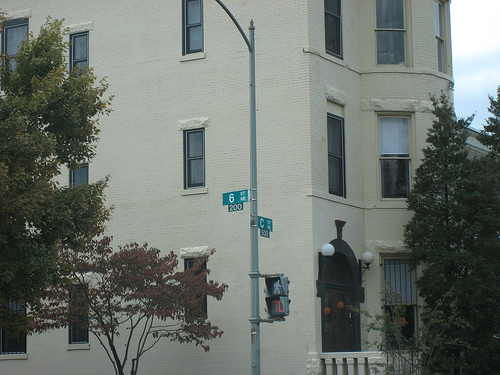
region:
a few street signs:
[218, 185, 279, 245]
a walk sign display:
[258, 273, 290, 296]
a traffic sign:
[263, 272, 298, 319]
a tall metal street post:
[236, 50, 265, 363]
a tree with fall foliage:
[31, 234, 228, 370]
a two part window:
[177, 119, 217, 197]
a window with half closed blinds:
[376, 101, 416, 212]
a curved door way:
[318, 234, 370, 366]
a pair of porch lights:
[317, 244, 374, 273]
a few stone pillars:
[318, 350, 384, 371]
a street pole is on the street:
[244, 22, 263, 372]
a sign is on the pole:
[219, 187, 250, 209]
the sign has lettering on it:
[223, 188, 246, 206]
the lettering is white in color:
[223, 187, 248, 202]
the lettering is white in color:
[255, 215, 270, 232]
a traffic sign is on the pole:
[263, 272, 292, 299]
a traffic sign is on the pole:
[263, 295, 291, 317]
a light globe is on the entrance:
[322, 241, 333, 256]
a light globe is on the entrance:
[362, 250, 372, 261]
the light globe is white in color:
[322, 245, 335, 257]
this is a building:
[110, 15, 408, 254]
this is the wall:
[103, 16, 179, 143]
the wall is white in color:
[136, 72, 206, 127]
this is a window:
[376, 117, 411, 189]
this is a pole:
[237, 25, 264, 372]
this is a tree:
[416, 104, 487, 371]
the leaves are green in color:
[426, 145, 463, 222]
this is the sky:
[451, 20, 491, 104]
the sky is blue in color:
[466, 50, 499, 115]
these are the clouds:
[453, 5, 488, 50]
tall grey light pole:
[240, 36, 282, 369]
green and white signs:
[221, 185, 278, 244]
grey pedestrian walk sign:
[261, 272, 298, 331]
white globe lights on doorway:
[302, 230, 399, 291]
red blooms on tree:
[96, 249, 238, 364]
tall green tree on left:
[0, 40, 122, 374]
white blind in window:
[375, 112, 418, 169]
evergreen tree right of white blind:
[400, 131, 497, 372]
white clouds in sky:
[464, 12, 499, 102]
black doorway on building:
[305, 195, 386, 352]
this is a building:
[276, 61, 319, 148]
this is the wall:
[266, 31, 308, 108]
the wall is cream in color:
[267, 53, 309, 137]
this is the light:
[317, 243, 340, 257]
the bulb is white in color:
[317, 243, 335, 258]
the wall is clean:
[133, 60, 193, 112]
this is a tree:
[423, 183, 498, 306]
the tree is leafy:
[412, 160, 489, 277]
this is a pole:
[230, 106, 269, 174]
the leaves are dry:
[121, 255, 184, 302]